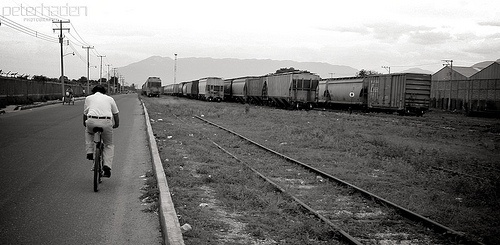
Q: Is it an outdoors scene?
A: Yes, it is outdoors.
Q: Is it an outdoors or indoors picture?
A: It is outdoors.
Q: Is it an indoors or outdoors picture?
A: It is outdoors.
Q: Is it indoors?
A: No, it is outdoors.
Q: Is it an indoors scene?
A: No, it is outdoors.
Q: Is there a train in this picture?
A: Yes, there is a train.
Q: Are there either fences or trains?
A: Yes, there is a train.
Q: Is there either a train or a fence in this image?
A: Yes, there is a train.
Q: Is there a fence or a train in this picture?
A: Yes, there is a train.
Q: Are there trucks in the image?
A: No, there are no trucks.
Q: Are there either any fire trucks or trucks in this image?
A: No, there are no trucks or fire trucks.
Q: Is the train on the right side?
A: Yes, the train is on the right of the image.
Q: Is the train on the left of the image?
A: No, the train is on the right of the image.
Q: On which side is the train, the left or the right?
A: The train is on the right of the image.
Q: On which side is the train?
A: The train is on the right of the image.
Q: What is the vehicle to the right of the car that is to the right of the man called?
A: The vehicle is a train.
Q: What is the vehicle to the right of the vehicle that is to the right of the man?
A: The vehicle is a train.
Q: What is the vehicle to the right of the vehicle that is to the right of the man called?
A: The vehicle is a train.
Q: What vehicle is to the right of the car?
A: The vehicle is a train.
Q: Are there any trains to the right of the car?
A: Yes, there is a train to the right of the car.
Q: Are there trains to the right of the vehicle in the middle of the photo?
A: Yes, there is a train to the right of the car.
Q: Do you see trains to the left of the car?
A: No, the train is to the right of the car.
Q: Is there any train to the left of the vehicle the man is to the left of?
A: No, the train is to the right of the car.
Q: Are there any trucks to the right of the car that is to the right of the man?
A: No, there is a train to the right of the car.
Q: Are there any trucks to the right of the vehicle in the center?
A: No, there is a train to the right of the car.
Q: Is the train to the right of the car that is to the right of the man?
A: Yes, the train is to the right of the car.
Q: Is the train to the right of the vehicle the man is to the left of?
A: Yes, the train is to the right of the car.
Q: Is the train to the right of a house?
A: No, the train is to the right of the car.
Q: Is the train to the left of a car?
A: No, the train is to the right of a car.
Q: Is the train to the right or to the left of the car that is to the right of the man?
A: The train is to the right of the car.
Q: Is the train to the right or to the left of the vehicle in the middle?
A: The train is to the right of the car.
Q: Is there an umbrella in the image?
A: No, there are no umbrellas.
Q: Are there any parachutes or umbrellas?
A: No, there are no umbrellas or parachutes.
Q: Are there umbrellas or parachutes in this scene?
A: No, there are no umbrellas or parachutes.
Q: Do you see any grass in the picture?
A: Yes, there is grass.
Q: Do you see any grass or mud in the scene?
A: Yes, there is grass.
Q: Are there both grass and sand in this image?
A: No, there is grass but no sand.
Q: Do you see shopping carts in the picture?
A: No, there are no shopping carts.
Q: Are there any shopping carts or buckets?
A: No, there are no shopping carts or buckets.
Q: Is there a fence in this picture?
A: Yes, there is a fence.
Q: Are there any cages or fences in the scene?
A: Yes, there is a fence.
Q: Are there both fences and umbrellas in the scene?
A: No, there is a fence but no umbrellas.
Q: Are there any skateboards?
A: No, there are no skateboards.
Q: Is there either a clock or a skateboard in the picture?
A: No, there are no skateboards or clocks.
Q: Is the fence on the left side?
A: Yes, the fence is on the left of the image.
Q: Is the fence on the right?
A: No, the fence is on the left of the image.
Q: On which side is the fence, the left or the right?
A: The fence is on the left of the image.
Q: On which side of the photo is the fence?
A: The fence is on the left of the image.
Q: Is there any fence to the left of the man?
A: Yes, there is a fence to the left of the man.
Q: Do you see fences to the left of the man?
A: Yes, there is a fence to the left of the man.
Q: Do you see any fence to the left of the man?
A: Yes, there is a fence to the left of the man.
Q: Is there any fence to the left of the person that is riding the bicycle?
A: Yes, there is a fence to the left of the man.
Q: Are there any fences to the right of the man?
A: No, the fence is to the left of the man.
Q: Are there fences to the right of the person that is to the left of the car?
A: No, the fence is to the left of the man.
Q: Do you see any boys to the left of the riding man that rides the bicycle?
A: No, there is a fence to the left of the man.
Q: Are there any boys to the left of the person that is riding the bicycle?
A: No, there is a fence to the left of the man.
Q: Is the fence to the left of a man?
A: Yes, the fence is to the left of a man.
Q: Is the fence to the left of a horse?
A: No, the fence is to the left of a man.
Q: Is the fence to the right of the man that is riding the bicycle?
A: No, the fence is to the left of the man.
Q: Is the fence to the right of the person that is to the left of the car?
A: No, the fence is to the left of the man.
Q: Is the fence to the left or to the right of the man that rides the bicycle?
A: The fence is to the left of the man.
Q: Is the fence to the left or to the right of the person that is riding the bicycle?
A: The fence is to the left of the man.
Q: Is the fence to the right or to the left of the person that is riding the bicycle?
A: The fence is to the left of the man.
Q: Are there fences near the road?
A: Yes, there is a fence near the road.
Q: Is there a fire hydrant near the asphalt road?
A: No, there is a fence near the road.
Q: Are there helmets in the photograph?
A: No, there are no helmets.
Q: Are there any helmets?
A: No, there are no helmets.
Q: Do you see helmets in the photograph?
A: No, there are no helmets.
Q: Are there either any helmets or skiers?
A: No, there are no helmets or skiers.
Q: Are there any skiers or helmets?
A: No, there are no helmets or skiers.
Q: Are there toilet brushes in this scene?
A: No, there are no toilet brushes.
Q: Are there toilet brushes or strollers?
A: No, there are no toilet brushes or strollers.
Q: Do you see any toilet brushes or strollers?
A: No, there are no toilet brushes or strollers.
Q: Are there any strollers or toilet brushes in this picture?
A: No, there are no toilet brushes or strollers.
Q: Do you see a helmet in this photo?
A: No, there are no helmets.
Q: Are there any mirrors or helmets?
A: No, there are no helmets or mirrors.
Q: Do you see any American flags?
A: No, there are no American flags.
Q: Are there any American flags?
A: No, there are no American flags.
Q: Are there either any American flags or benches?
A: No, there are no American flags or benches.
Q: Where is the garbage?
A: The garbage is on the road.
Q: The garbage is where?
A: The garbage is on the road.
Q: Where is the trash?
A: The garbage is on the road.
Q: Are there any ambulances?
A: No, there are no ambulances.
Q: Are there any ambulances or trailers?
A: No, there are no ambulances or trailers.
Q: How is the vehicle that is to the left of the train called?
A: The vehicle is a car.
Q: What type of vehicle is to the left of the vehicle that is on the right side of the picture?
A: The vehicle is a car.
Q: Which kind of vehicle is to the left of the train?
A: The vehicle is a car.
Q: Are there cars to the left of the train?
A: Yes, there is a car to the left of the train.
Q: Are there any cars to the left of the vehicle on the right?
A: Yes, there is a car to the left of the train.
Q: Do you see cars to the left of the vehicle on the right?
A: Yes, there is a car to the left of the train.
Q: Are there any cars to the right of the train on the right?
A: No, the car is to the left of the train.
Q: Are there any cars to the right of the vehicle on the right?
A: No, the car is to the left of the train.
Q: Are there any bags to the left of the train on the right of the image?
A: No, there is a car to the left of the train.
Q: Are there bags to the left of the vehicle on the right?
A: No, there is a car to the left of the train.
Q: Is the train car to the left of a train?
A: Yes, the car is to the left of a train.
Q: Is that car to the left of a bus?
A: No, the car is to the left of a train.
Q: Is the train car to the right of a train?
A: No, the car is to the left of a train.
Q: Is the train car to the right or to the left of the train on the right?
A: The car is to the left of the train.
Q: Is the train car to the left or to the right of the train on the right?
A: The car is to the left of the train.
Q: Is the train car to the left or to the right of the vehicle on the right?
A: The car is to the left of the train.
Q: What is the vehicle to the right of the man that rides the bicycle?
A: The vehicle is a car.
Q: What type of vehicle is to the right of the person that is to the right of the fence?
A: The vehicle is a car.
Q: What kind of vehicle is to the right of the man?
A: The vehicle is a car.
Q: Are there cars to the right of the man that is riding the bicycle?
A: Yes, there is a car to the right of the man.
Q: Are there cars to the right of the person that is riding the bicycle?
A: Yes, there is a car to the right of the man.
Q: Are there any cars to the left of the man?
A: No, the car is to the right of the man.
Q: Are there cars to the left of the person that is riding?
A: No, the car is to the right of the man.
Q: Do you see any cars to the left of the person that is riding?
A: No, the car is to the right of the man.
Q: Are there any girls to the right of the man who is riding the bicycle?
A: No, there is a car to the right of the man.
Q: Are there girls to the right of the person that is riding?
A: No, there is a car to the right of the man.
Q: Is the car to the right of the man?
A: Yes, the car is to the right of the man.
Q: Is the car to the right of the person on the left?
A: Yes, the car is to the right of the man.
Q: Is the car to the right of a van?
A: No, the car is to the right of the man.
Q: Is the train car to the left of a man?
A: No, the car is to the right of a man.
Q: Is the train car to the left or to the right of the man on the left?
A: The car is to the right of the man.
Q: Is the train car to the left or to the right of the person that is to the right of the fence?
A: The car is to the right of the man.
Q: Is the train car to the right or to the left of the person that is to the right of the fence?
A: The car is to the right of the man.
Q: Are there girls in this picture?
A: No, there are no girls.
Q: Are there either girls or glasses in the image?
A: No, there are no girls or glasses.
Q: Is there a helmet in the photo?
A: No, there are no helmets.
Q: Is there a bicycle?
A: Yes, there is a bicycle.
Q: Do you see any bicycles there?
A: Yes, there is a bicycle.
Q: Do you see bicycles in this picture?
A: Yes, there is a bicycle.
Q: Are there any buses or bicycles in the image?
A: Yes, there is a bicycle.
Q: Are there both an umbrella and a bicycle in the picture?
A: No, there is a bicycle but no umbrellas.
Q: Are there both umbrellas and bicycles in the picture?
A: No, there is a bicycle but no umbrellas.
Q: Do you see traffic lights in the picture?
A: No, there are no traffic lights.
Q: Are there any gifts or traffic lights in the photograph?
A: No, there are no traffic lights or gifts.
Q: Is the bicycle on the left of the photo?
A: Yes, the bicycle is on the left of the image.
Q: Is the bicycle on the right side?
A: No, the bicycle is on the left of the image.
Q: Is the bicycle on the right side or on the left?
A: The bicycle is on the left of the image.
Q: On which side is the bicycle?
A: The bicycle is on the left of the image.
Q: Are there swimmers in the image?
A: No, there are no swimmers.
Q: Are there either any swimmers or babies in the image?
A: No, there are no swimmers or babies.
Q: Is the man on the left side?
A: Yes, the man is on the left of the image.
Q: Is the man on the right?
A: No, the man is on the left of the image.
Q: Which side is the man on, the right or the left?
A: The man is on the left of the image.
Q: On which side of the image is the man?
A: The man is on the left of the image.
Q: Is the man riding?
A: Yes, the man is riding.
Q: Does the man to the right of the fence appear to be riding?
A: Yes, the man is riding.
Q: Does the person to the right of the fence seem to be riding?
A: Yes, the man is riding.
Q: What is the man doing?
A: The man is riding.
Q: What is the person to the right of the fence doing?
A: The man is riding.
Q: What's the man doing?
A: The man is riding.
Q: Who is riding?
A: The man is riding.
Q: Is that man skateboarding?
A: No, the man is riding.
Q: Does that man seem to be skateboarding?
A: No, the man is riding.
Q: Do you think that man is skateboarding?
A: No, the man is riding.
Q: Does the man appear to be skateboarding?
A: No, the man is riding.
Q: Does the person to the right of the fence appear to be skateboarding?
A: No, the man is riding.